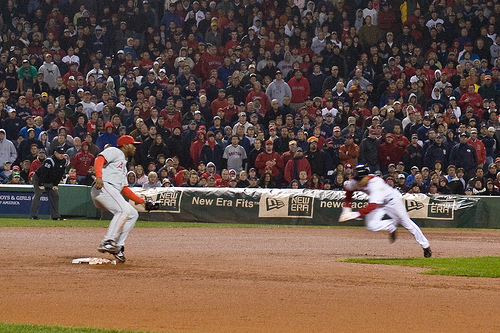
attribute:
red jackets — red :
[254, 137, 321, 196]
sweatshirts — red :
[259, 139, 323, 193]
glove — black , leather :
[144, 193, 174, 220]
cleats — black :
[95, 240, 130, 270]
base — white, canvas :
[74, 257, 128, 267]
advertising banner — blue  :
[3, 186, 58, 220]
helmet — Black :
[344, 164, 374, 180]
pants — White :
[352, 190, 450, 274]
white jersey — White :
[345, 180, 402, 221]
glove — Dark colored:
[147, 193, 170, 212]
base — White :
[75, 254, 116, 264]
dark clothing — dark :
[28, 140, 70, 218]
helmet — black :
[346, 164, 376, 184]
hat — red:
[114, 133, 136, 145]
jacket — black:
[33, 154, 66, 187]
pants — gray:
[29, 182, 59, 221]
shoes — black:
[29, 212, 63, 221]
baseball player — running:
[336, 163, 434, 260]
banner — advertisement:
[118, 182, 472, 227]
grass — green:
[340, 237, 493, 279]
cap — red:
[115, 134, 145, 147]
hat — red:
[113, 135, 143, 145]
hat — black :
[52, 144, 66, 154]